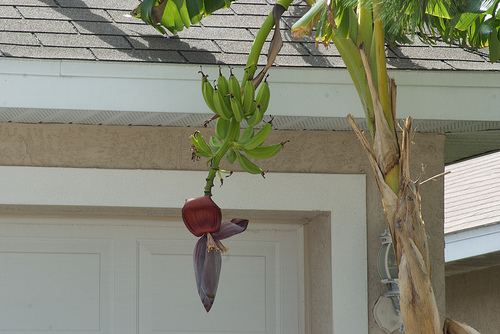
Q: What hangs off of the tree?
A: Bunch of bananas.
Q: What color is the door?
A: White.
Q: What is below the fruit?
A: Flower.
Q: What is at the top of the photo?
A: Roof of garage.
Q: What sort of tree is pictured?
A: Small banana tree.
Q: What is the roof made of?
A: Shingles.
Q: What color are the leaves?
A: Green.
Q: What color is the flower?
A: Red.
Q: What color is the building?
A: Beige.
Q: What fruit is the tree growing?
A: Bananas.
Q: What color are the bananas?
A: Green.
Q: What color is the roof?
A: Brown.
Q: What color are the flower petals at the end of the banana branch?
A: Purple.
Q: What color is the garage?
A: White.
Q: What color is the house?
A: Brown.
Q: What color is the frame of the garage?
A: White.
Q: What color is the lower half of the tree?
A: Brown.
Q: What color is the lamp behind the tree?
A: White.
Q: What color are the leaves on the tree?
A: Green.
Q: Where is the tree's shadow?
A: On the roof.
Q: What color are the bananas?
A: Green.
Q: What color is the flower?
A: Red.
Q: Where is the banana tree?
A: In front of a house.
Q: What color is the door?
A: White.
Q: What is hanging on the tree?
A: Bananas.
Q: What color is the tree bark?
A: Brown.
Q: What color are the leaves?
A: Green.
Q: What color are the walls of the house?
A: Tan.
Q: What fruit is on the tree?
A: Bananas.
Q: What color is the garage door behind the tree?
A: White.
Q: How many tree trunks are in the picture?
A: 1.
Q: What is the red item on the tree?
A: A flower.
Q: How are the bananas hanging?
A: On the tree.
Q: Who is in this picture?
A: Nobody.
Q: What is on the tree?
A: Bananas.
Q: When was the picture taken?
A: During the day.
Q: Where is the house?
A: Behind the tree.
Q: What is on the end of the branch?
A: A flower.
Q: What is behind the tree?
A: A house.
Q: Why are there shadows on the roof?
A: It is sunny.